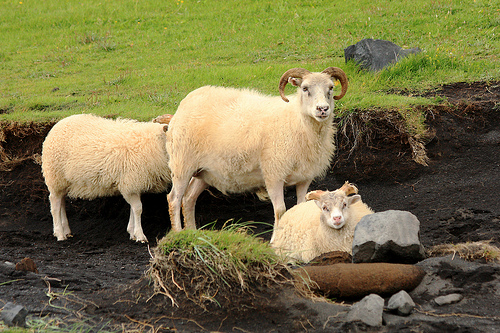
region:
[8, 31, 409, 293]
sheep standing together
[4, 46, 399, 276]
large white sheep together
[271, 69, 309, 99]
brown horns on ram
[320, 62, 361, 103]
brown horn on a aram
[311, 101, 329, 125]
small black snout of ram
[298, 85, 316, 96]
black eye of ram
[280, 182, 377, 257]
small baby ram laying down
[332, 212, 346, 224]
small orange nose of ram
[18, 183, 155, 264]
white legs of ram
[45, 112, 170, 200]
fluffy body of ram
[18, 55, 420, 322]
three rams all together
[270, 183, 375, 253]
baby ram laying down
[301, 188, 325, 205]
small horn on baby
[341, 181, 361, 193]
small horn on ram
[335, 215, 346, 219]
pink front nose of ram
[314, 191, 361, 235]
small white face of ram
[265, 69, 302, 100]
large brown horn of ram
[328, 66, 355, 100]
large brown horn of ram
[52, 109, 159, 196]
white fluffy fur of ram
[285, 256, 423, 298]
brown rock in creek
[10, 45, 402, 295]
three rams standing together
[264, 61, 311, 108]
brown horn of ram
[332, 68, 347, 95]
brown horn of ram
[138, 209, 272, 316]
green top to bushes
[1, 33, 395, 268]
rams standing in a creek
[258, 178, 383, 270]
baby ram laying down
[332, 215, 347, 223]
small orange nose on ram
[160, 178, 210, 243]
long white leg of ram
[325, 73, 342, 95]
small black eye of ram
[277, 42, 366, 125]
head of a goat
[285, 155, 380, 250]
head of a goat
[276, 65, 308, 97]
ear of a goat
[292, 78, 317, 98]
eye of a goat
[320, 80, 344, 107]
eye of a goat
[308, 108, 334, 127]
mouth of a goat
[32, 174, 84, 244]
leg of a goat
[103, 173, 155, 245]
leg of a goat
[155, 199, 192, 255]
leg of a goat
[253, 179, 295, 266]
leg of a goat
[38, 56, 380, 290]
three rams next to each other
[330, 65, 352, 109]
brown horn of ram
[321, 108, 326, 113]
small pink nose of ram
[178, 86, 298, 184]
white fur of ram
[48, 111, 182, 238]
white fur of small ram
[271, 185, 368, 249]
baby ram laying on the ground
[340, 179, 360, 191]
orange small horn of ram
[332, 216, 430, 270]
large grey rock on ground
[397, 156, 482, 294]
empty river bed by field